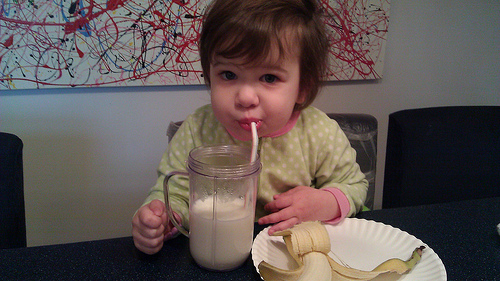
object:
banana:
[257, 221, 427, 280]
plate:
[249, 216, 448, 281]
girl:
[131, 1, 370, 255]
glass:
[162, 145, 262, 273]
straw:
[244, 122, 258, 209]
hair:
[197, 0, 332, 113]